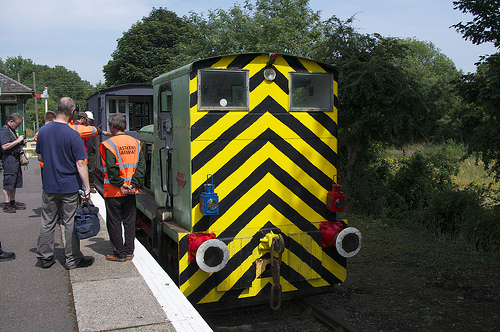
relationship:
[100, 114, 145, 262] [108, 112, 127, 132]
man has hair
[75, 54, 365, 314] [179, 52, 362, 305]
train has back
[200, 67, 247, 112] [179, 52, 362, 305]
window on top of back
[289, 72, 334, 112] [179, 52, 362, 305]
window on top of back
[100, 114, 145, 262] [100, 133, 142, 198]
man wearing vest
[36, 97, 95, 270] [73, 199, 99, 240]
man holding pack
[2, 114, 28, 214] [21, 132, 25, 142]
man looking at camera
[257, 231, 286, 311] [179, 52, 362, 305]
hitch attached on back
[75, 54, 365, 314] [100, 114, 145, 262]
train behind man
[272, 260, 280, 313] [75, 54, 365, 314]
chain hanging from train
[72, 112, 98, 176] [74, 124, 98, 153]
man in vest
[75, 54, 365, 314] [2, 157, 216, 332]
train has platform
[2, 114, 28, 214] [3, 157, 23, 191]
man wearing shorts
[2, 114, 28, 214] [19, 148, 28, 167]
man holding pack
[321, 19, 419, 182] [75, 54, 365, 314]
tree on far side of train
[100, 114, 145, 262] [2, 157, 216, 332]
man standing on platform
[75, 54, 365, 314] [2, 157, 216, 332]
train boarding platform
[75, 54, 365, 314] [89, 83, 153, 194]
train has car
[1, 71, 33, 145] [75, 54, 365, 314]
building for train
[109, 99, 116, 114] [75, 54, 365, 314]
window on train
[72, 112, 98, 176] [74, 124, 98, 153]
man wearing vest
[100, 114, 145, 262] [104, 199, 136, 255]
man wearing pants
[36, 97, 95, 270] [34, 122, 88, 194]
man wearing shirt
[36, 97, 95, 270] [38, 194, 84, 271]
man wearing pants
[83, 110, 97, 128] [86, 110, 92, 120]
man wearing helmet